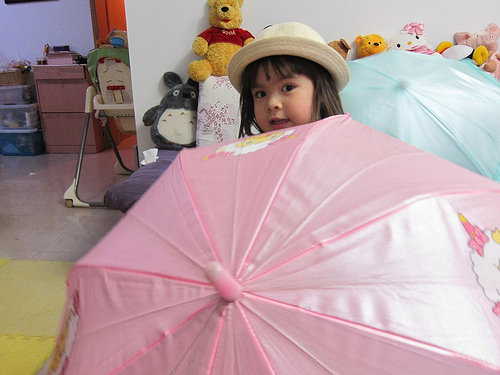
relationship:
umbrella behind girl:
[326, 47, 499, 182] [223, 16, 353, 138]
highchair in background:
[86, 31, 136, 173] [3, 0, 493, 208]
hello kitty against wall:
[387, 20, 440, 64] [123, 3, 500, 176]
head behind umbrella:
[203, 1, 247, 29] [37, 108, 500, 374]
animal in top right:
[453, 18, 500, 88] [410, 0, 498, 160]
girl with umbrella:
[223, 16, 353, 138] [37, 108, 500, 374]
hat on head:
[227, 22, 351, 93] [238, 53, 346, 137]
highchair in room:
[86, 31, 136, 173] [37, 108, 500, 374]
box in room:
[3, 54, 31, 85] [11, 5, 498, 367]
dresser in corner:
[34, 58, 95, 156] [3, 0, 145, 312]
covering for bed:
[104, 145, 184, 212] [101, 139, 199, 216]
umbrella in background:
[37, 108, 500, 374] [3, 0, 493, 208]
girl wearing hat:
[223, 16, 353, 138] [227, 22, 351, 93]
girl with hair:
[223, 16, 353, 138] [233, 56, 345, 140]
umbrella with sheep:
[37, 108, 500, 374] [218, 124, 298, 160]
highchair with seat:
[86, 31, 136, 173] [84, 46, 135, 108]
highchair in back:
[86, 31, 136, 173] [4, 1, 142, 194]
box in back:
[3, 54, 31, 85] [4, 1, 142, 194]